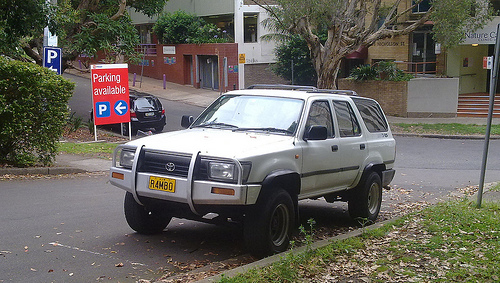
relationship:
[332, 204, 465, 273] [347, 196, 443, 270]
leaves on ground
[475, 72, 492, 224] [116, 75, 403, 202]
pole by suv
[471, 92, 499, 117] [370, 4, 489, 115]
stair by building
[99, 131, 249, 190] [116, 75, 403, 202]
headlights of suv